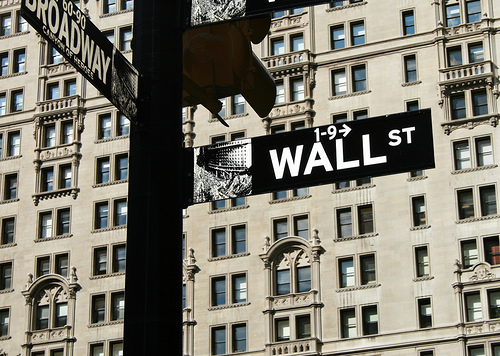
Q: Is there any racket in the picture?
A: No, there are no rackets.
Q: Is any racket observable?
A: No, there are no rackets.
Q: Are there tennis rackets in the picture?
A: No, there are no tennis rackets.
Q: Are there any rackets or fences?
A: No, there are no rackets or fences.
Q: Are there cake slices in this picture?
A: No, there are no cake slices.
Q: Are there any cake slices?
A: No, there are no cake slices.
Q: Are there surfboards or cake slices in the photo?
A: No, there are no cake slices or surfboards.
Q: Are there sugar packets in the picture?
A: No, there are no sugar packets.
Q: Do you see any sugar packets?
A: No, there are no sugar packets.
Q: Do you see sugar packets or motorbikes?
A: No, there are no sugar packets or motorbikes.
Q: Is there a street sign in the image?
A: Yes, there is a street sign.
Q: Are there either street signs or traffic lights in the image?
A: Yes, there is a street sign.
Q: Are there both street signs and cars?
A: No, there is a street sign but no cars.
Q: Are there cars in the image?
A: No, there are no cars.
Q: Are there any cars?
A: No, there are no cars.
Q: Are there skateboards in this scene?
A: No, there are no skateboards.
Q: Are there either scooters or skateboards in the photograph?
A: No, there are no skateboards or scooters.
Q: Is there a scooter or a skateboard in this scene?
A: No, there are no skateboards or scooters.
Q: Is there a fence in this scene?
A: No, there are no fences.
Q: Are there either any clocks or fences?
A: No, there are no fences or clocks.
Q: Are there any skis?
A: No, there are no skis.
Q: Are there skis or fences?
A: No, there are no skis or fences.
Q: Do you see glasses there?
A: No, there are no glasses.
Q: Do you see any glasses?
A: No, there are no glasses.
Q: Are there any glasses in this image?
A: No, there are no glasses.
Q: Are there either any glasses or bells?
A: No, there are no glasses or bells.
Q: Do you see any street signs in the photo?
A: Yes, there is a street sign.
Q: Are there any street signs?
A: Yes, there is a street sign.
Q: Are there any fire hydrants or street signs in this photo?
A: Yes, there is a street sign.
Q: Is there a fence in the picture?
A: No, there are no fences.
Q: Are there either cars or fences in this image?
A: No, there are no fences or cars.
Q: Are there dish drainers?
A: No, there are no dish drainers.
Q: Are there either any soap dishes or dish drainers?
A: No, there are no dish drainers or soap dishes.